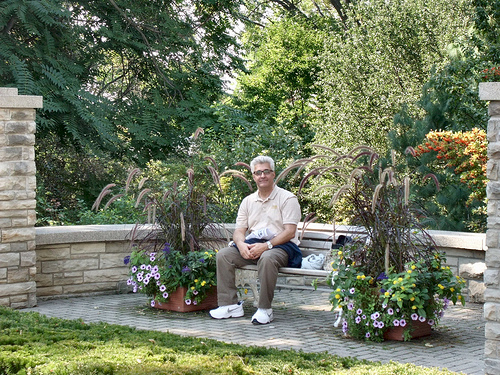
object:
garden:
[0, 79, 499, 375]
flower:
[346, 286, 356, 296]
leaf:
[457, 140, 471, 154]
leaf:
[457, 280, 461, 290]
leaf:
[122, 101, 137, 114]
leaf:
[459, 293, 466, 308]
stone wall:
[33, 221, 490, 315]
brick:
[37, 255, 101, 275]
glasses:
[249, 167, 276, 176]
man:
[207, 154, 303, 327]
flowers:
[159, 290, 171, 300]